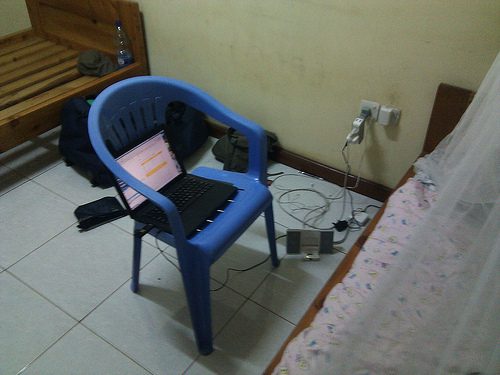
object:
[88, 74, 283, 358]
chair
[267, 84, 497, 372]
bed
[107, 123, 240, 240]
laptop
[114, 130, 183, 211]
screen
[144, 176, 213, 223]
keyboard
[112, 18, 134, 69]
bottle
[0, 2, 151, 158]
bed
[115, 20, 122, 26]
bottle cap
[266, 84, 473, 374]
frame of bed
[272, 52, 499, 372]
tulle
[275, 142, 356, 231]
wires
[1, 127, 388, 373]
floor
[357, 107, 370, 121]
plugs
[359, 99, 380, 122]
outlet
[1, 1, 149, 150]
frame of bed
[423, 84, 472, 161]
headboard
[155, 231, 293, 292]
wire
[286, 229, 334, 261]
stereo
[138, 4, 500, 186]
wall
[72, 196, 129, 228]
object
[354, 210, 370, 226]
ipod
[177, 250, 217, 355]
leg of chair